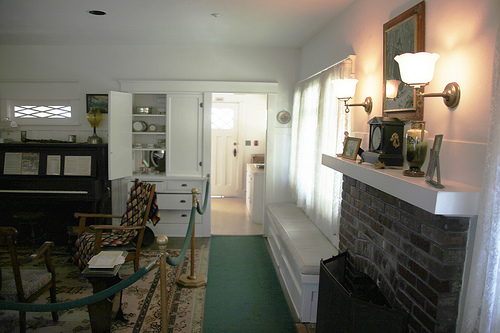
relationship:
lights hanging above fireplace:
[324, 50, 459, 115] [318, 149, 476, 331]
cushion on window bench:
[251, 161, 354, 293] [264, 150, 368, 300]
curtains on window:
[287, 60, 354, 237] [286, 52, 353, 245]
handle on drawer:
[180, 180, 190, 187] [167, 179, 202, 188]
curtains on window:
[292, 63, 354, 235] [293, 65, 352, 235]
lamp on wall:
[392, 53, 467, 119] [299, 0, 499, 185]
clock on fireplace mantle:
[367, 113, 406, 166] [320, 150, 481, 217]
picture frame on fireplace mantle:
[419, 132, 450, 190] [318, 144, 478, 225]